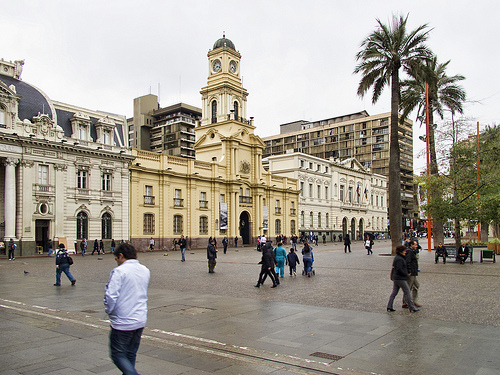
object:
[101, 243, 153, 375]
person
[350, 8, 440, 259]
trees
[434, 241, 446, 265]
people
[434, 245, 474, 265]
bench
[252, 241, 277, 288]
people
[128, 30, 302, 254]
building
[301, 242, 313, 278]
woman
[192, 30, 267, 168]
tower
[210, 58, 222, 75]
clock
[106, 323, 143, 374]
jeans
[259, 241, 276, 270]
jacket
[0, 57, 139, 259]
buildings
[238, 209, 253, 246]
doorways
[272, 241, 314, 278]
family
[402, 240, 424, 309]
man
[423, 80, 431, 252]
pole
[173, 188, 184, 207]
window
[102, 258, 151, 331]
shirt